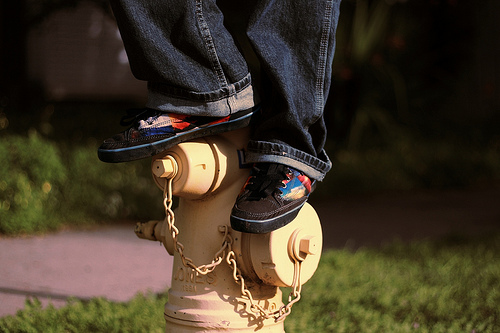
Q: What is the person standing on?
A: Fire hydrant.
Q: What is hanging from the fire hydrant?
A: Chains.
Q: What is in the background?
A: Sidewalk.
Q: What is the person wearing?
A: Blue jeans.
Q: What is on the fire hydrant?
A: A person..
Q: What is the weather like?
A: Sunny.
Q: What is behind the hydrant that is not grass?
A: Cement sidewalk.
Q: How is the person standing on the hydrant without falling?
A: Balance.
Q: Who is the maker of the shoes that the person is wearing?
A: Converse.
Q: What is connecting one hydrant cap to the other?
A: Small chain links.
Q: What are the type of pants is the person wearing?
A: Dark blue jeans.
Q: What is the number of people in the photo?
A: One.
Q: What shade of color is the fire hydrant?
A: Yellow.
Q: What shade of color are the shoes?
A: Black.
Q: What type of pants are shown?
A: Jeans.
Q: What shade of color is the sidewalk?
A: Gray.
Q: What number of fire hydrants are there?
A: 1.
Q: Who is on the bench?
A: There is no bench.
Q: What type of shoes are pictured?
A: Sneakers.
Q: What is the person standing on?
A: A fire hydrant.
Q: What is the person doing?
A: Standing on a fire hydrant.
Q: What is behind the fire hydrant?
A: Grass and sidewalk.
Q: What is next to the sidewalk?
A: Grass.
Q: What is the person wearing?
A: Dark pants.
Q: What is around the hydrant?
A: Green grass.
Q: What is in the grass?
A: A yellow fire hydrant.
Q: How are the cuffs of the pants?
A: Rolled up.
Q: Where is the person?
A: Standing on a fire hydrant.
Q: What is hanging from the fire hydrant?
A: Chains.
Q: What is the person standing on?
A: Yellow fire hydrant.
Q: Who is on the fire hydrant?
A: Person in black sneakers.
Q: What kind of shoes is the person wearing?
A: Black sneakers.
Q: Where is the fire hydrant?
A: The ground.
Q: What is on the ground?
A: A sidewalk.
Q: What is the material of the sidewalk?
A: Concrete.